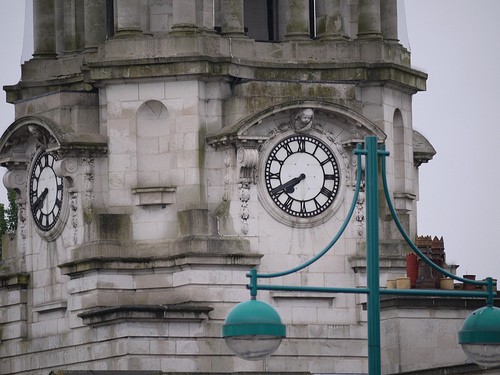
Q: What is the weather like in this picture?
A: It is cloudy.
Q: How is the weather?
A: It is cloudy.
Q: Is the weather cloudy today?
A: Yes, it is cloudy.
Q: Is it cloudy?
A: Yes, it is cloudy.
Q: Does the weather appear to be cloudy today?
A: Yes, it is cloudy.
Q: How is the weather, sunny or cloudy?
A: It is cloudy.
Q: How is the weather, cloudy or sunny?
A: It is cloudy.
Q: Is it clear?
A: No, it is cloudy.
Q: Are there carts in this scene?
A: No, there are no carts.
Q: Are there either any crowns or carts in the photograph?
A: No, there are no carts or crowns.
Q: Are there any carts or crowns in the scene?
A: No, there are no carts or crowns.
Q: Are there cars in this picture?
A: No, there are no cars.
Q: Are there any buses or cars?
A: No, there are no cars or buses.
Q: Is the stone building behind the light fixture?
A: Yes, the building is behind the light fixture.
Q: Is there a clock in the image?
A: Yes, there is a clock.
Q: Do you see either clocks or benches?
A: Yes, there is a clock.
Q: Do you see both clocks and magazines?
A: No, there is a clock but no magazines.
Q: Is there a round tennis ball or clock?
A: Yes, there is a round clock.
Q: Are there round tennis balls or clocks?
A: Yes, there is a round clock.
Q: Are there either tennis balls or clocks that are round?
A: Yes, the clock is round.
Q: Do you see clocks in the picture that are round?
A: Yes, there is a round clock.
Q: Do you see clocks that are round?
A: Yes, there is a clock that is round.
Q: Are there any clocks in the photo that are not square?
A: Yes, there is a round clock.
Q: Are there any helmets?
A: No, there are no helmets.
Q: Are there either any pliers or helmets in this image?
A: No, there are no helmets or pliers.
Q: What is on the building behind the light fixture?
A: The clock is on the building.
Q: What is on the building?
A: The clock is on the building.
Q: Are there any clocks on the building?
A: Yes, there is a clock on the building.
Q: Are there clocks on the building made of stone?
A: Yes, there is a clock on the building.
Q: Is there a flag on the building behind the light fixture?
A: No, there is a clock on the building.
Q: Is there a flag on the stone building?
A: No, there is a clock on the building.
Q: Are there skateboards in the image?
A: No, there are no skateboards.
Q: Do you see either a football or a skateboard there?
A: No, there are no skateboards or footballs.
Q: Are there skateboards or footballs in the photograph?
A: No, there are no skateboards or footballs.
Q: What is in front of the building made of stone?
A: The light fixture is in front of the building.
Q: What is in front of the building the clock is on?
A: The light fixture is in front of the building.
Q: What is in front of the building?
A: The light fixture is in front of the building.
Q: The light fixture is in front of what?
A: The light fixture is in front of the building.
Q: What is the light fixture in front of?
A: The light fixture is in front of the building.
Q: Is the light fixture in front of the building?
A: Yes, the light fixture is in front of the building.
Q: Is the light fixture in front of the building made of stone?
A: Yes, the light fixture is in front of the building.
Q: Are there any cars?
A: No, there are no cars.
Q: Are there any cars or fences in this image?
A: No, there are no cars or fences.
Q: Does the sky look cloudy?
A: Yes, the sky is cloudy.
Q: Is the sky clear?
A: No, the sky is cloudy.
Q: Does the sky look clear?
A: No, the sky is cloudy.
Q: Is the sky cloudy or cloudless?
A: The sky is cloudy.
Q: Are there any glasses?
A: No, there are no glasses.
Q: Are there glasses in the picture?
A: No, there are no glasses.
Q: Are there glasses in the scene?
A: No, there are no glasses.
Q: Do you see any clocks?
A: Yes, there is a clock.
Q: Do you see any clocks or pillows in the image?
A: Yes, there is a clock.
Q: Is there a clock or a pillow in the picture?
A: Yes, there is a clock.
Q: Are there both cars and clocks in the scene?
A: No, there is a clock but no cars.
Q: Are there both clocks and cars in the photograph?
A: No, there is a clock but no cars.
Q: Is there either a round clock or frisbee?
A: Yes, there is a round clock.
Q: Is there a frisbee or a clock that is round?
A: Yes, the clock is round.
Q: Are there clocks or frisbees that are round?
A: Yes, the clock is round.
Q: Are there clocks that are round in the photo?
A: Yes, there is a round clock.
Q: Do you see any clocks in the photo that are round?
A: Yes, there is a clock that is round.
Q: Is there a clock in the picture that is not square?
A: Yes, there is a round clock.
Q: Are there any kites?
A: No, there are no kites.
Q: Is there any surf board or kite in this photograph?
A: No, there are no kites or surfboards.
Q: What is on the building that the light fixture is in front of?
A: The clock is on the building.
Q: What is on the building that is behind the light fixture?
A: The clock is on the building.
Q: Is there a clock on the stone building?
A: Yes, there is a clock on the building.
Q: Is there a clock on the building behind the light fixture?
A: Yes, there is a clock on the building.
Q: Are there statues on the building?
A: No, there is a clock on the building.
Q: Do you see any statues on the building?
A: No, there is a clock on the building.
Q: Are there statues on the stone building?
A: No, there is a clock on the building.